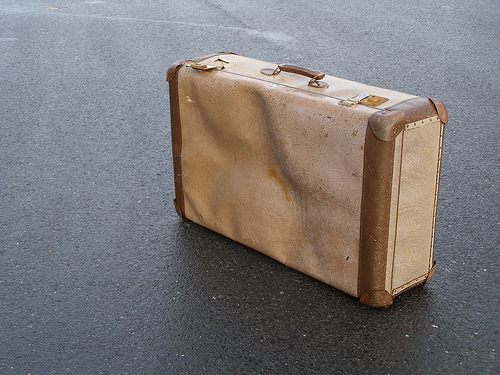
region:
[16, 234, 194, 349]
road that is paved with very dark asphalt.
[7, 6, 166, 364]
Road that appears to be wet from rain.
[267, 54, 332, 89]
Dark brown handle on suitcase.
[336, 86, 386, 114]
Fastener on top of the suitcase to hold it closed.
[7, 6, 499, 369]
Suitcase standing upright on the road.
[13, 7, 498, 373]
Suitcase sitting outside in the daylight.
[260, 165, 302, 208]
Stain on the side of the suitcase.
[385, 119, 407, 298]
Stitching on the side of the suitcase.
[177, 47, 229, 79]
Buckle on the top of the suitcase that is open.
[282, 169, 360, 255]
the suitcase is tan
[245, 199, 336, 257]
the suitcase is boxy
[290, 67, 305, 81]
this is a handle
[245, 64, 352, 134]
the handle is leather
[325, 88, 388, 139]
the latch is brass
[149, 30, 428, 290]
suitcase on the pavement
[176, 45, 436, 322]
suitcase on the pavement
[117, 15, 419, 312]
suitcase on the pavement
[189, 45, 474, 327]
suitcase on the pavement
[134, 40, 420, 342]
suitcase on the pavement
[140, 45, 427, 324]
suitcase on the pavement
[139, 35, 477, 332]
Suitcase on the pavement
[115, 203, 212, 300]
The pavement is dark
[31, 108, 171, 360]
Pavement is wet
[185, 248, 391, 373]
Shadow on the pavement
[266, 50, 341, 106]
Handle on the suit case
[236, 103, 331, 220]
Dirt on side of suitcase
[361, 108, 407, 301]
Plastic on side of luggage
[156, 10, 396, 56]
Dry spot on the ground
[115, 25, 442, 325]
Small brown suitcase on the pavement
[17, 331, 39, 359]
Small white specks on the pavement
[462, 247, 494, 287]
Small white specks on the pavement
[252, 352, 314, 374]
Small white specks on the pavement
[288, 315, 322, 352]
Small white specks on the pavement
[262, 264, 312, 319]
Small white specks on the pavement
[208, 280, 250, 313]
Small white specks on the pavement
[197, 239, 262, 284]
Small white specks on the pavement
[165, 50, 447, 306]
the luggage is light brown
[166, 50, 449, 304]
the luggage is standing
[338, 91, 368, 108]
the latch is gold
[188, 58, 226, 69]
the latch is gold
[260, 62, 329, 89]
the handle is brown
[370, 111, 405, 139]
the corner protector is brown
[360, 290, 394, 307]
the corner protector is brown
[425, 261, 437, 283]
the corner protector is brown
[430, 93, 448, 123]
the corner protector is brown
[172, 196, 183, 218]
the corner protector is brown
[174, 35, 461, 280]
a brown suitcase on the ground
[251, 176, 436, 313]
a brown suitcase on the ground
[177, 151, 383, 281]
a brown suitcase on the grounda brown suitcase on the ground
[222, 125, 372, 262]
a brown suitcase on the ground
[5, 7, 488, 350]
suitcase on the ground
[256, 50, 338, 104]
brown hand on suitcase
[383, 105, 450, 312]
rivets on the suitcase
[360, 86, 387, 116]
clasp on the suitcase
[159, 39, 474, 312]
the suitcase is tan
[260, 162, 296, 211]
brown mark on suitcase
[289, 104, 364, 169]
spots on the suitcase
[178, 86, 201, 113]
white mark on the suitcase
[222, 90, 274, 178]
dent in the suitcase